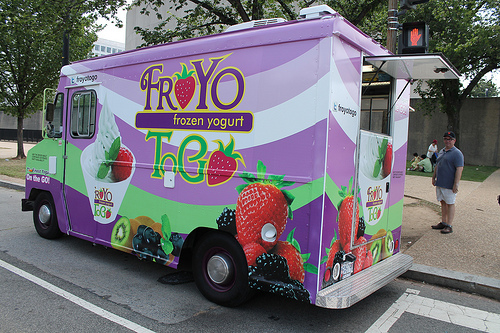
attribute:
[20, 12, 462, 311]
truck — frozen yogurt to go, purple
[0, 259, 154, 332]
line — white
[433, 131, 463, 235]
man — standing, staring at camera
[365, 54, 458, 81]
overhead access door — open